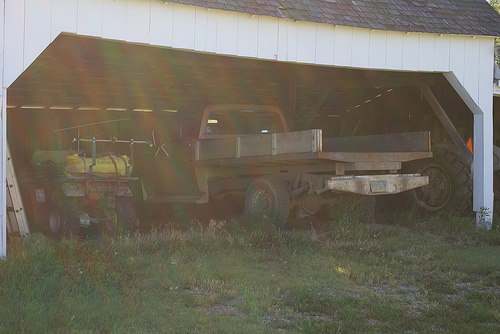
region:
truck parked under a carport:
[156, 88, 452, 226]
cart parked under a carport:
[20, 113, 150, 233]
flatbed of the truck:
[205, 127, 445, 176]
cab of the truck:
[147, 102, 284, 189]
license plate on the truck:
[368, 179, 390, 194]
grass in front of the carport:
[17, 222, 489, 330]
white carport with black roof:
[5, 4, 499, 224]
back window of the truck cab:
[197, 105, 277, 133]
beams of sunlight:
[15, 30, 441, 278]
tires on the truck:
[231, 182, 367, 228]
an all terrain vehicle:
[24, 148, 143, 245]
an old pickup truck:
[146, 100, 434, 232]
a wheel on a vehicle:
[246, 178, 283, 226]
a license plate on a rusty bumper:
[368, 175, 389, 197]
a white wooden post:
[468, 96, 495, 221]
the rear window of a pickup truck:
[202, 102, 286, 141]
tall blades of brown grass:
[118, 222, 216, 247]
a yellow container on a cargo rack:
[60, 148, 137, 185]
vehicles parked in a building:
[13, 25, 480, 254]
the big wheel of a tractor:
[409, 148, 468, 217]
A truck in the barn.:
[135, 97, 442, 221]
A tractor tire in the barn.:
[401, 143, 474, 213]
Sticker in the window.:
[198, 110, 231, 135]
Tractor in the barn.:
[17, 119, 158, 239]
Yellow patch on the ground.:
[328, 255, 363, 285]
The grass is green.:
[12, 260, 174, 330]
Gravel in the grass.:
[207, 265, 482, 317]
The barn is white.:
[1, 0, 498, 270]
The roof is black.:
[217, 0, 499, 40]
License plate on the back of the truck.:
[363, 170, 397, 198]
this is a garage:
[180, 110, 302, 225]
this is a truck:
[171, 120, 319, 290]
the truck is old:
[150, 80, 325, 218]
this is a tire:
[220, 168, 265, 268]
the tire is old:
[221, 154, 294, 287]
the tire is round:
[236, 156, 319, 242]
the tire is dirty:
[203, 171, 266, 200]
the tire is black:
[180, 190, 281, 236]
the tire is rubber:
[245, 175, 335, 286]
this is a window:
[167, 98, 237, 159]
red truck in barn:
[70, 95, 387, 223]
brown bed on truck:
[187, 141, 409, 198]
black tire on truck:
[227, 171, 287, 228]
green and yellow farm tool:
[27, 132, 164, 232]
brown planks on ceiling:
[18, 42, 301, 124]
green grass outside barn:
[98, 231, 198, 318]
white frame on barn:
[0, 22, 472, 218]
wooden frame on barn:
[25, 21, 310, 61]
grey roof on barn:
[233, 5, 490, 47]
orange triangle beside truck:
[453, 131, 474, 160]